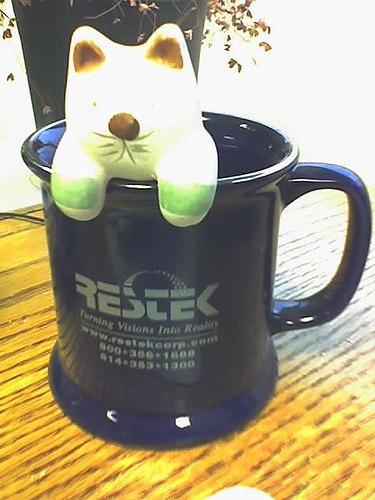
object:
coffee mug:
[21, 105, 370, 453]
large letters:
[73, 270, 98, 314]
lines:
[125, 269, 156, 285]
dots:
[172, 276, 177, 283]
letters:
[94, 277, 121, 318]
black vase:
[8, 1, 207, 130]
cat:
[47, 21, 214, 228]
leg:
[50, 141, 109, 224]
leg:
[154, 158, 219, 229]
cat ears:
[68, 24, 110, 73]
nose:
[108, 112, 141, 141]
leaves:
[1, 21, 20, 50]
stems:
[204, 0, 274, 61]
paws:
[51, 171, 102, 224]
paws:
[156, 174, 217, 227]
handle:
[274, 162, 373, 331]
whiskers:
[89, 128, 120, 143]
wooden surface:
[0, 188, 374, 500]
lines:
[268, 415, 375, 491]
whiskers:
[130, 128, 154, 142]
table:
[1, 184, 372, 498]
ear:
[145, 22, 191, 69]